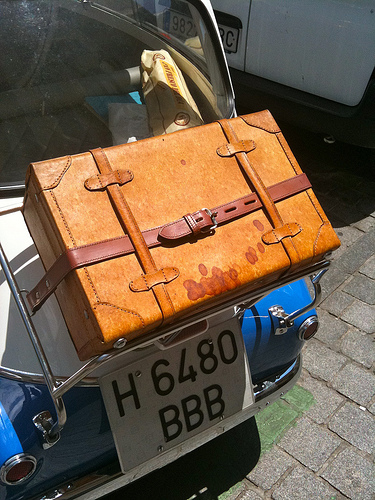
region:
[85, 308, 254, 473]
License plate on blue car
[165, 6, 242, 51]
license plate on white car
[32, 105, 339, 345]
leather suitcase strapped to rear of blue car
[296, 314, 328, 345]
right taillight of blue car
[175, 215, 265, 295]
stains on tan leather suitcase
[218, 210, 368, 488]
Cobblestone pavement under the cars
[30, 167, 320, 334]
strap holding tan leather suitcase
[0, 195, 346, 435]
Luggage rack on rear of blue car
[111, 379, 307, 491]
green paint on cobblestone under car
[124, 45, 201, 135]
Crumpled empty yellow container in trunk of blue car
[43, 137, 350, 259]
Light brown leather suitcase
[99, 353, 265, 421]
License plate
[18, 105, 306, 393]
A bright blue vintage car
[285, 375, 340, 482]
Bricked pavement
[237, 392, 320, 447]
A green stain on the bricked pavement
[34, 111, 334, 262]
A vintage leather suitcase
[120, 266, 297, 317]
Stains on the brown leather suitcase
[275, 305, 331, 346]
The round tail lights of the car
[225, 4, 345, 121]
The back of a white contemporary car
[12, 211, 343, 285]
Leather suitcase is strapped to the trunk of the car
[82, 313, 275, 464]
A white and black license plate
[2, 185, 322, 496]
back of a blue and white vehicle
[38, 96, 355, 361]
A large tan suitcase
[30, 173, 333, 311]
Brown leather strap across suitcase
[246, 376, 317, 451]
a green spot on the ground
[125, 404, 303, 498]
shadow of car on the ground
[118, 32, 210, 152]
a brown bag with yellow and red writing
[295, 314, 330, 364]
Small round tail light to vehicle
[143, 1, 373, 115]
Back of a white vehicle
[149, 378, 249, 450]
BBB in Black letters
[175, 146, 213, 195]
part of a suitcase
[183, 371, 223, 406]
part of a plate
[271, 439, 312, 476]
part of a floor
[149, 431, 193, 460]
erdge of a plate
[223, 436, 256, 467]
part of a shade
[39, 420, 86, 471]
back of a car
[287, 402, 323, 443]
part of a floor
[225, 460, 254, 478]
part of a shade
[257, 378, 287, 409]
edge of a car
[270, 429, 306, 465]
part of a floor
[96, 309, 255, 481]
license plate on old car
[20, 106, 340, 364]
suit case strapped to back of the car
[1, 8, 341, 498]
parked old blue car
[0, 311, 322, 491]
round blue tights on old car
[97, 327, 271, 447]
license plate with the numbers H6480 BBB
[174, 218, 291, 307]
damage on the suitcase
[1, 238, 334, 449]
silver luggage carrier on back of car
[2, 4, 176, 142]
dirty back glass in the car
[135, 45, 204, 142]
bag of fresh bread through the back glass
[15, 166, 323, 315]
brown strap holding the suitcase in place